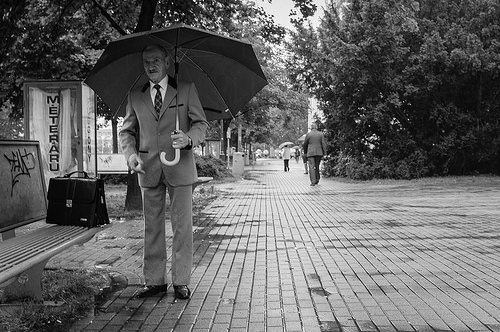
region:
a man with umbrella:
[55, 16, 295, 282]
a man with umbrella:
[72, 35, 287, 298]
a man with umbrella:
[70, 8, 295, 330]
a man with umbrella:
[72, 10, 295, 320]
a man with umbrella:
[77, 26, 239, 327]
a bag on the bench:
[25, 149, 130, 275]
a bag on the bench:
[33, 154, 146, 268]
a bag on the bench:
[27, 143, 135, 248]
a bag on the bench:
[14, 145, 137, 272]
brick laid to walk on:
[229, 315, 247, 327]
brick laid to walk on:
[248, 319, 265, 330]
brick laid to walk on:
[231, 308, 248, 316]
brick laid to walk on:
[248, 311, 263, 319]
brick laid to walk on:
[266, 305, 281, 315]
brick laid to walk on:
[283, 308, 298, 320]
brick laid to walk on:
[300, 303, 313, 313]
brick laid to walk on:
[426, 318, 447, 330]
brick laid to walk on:
[314, 310, 333, 322]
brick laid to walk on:
[241, 267, 253, 282]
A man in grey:
[75, 43, 255, 330]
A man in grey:
[294, 114, 328, 175]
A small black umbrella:
[78, 30, 270, 95]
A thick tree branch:
[398, 16, 475, 107]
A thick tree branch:
[431, 106, 496, 158]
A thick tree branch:
[307, 24, 359, 92]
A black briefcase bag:
[22, 136, 104, 228]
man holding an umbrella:
[90, 25, 268, 300]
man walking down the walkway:
[302, 119, 327, 184]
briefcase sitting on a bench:
[46, 171, 106, 228]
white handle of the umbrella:
[158, 112, 181, 166]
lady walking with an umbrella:
[281, 139, 293, 172]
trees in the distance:
[291, 0, 498, 180]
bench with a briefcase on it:
[1, 138, 114, 315]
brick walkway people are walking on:
[96, 158, 495, 329]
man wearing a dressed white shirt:
[146, 74, 168, 110]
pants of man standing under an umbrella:
[143, 185, 193, 284]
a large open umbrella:
[88, 19, 267, 165]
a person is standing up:
[123, 55, 209, 306]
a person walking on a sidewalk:
[296, 113, 327, 191]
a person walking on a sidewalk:
[282, 141, 292, 171]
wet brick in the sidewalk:
[281, 298, 297, 311]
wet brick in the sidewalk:
[283, 302, 293, 312]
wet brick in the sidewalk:
[282, 306, 299, 321]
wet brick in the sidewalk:
[262, 280, 277, 297]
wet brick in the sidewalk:
[262, 287, 273, 297]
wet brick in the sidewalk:
[268, 291, 279, 302]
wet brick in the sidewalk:
[266, 296, 277, 311]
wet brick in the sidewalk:
[250, 280, 270, 290]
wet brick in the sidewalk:
[248, 292, 265, 306]